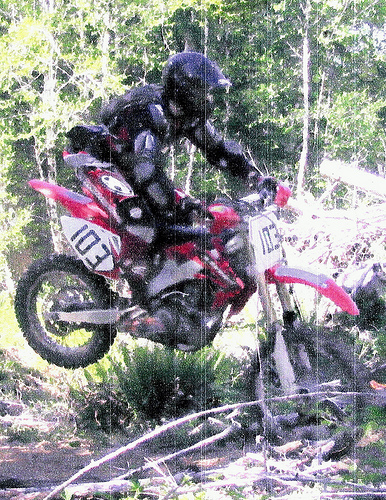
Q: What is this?
A: Motorcycle.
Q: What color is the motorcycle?
A: Red.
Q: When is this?
A: Daytime.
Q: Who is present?
A: Man.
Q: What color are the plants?
A: Green.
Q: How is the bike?
A: In motion.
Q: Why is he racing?
A: Competition.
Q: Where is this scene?
A: In nature.